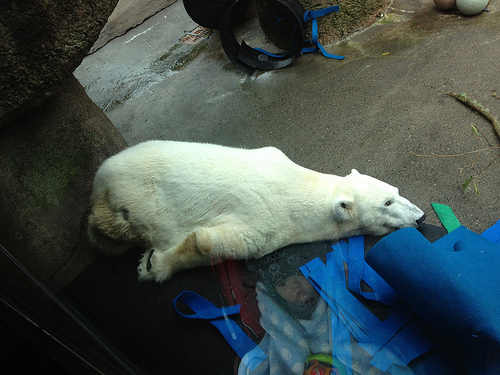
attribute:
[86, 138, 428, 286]
bear — white, big, laying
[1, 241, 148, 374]
wood — brown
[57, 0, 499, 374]
ground — scarred, hard, stone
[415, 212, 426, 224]
nose — black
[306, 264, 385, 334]
paper — blue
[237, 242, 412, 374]
child — reflected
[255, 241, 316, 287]
bandana — patterned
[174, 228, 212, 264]
spot — dark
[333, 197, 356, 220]
ear — small, white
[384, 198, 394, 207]
eye — black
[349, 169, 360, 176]
ear — white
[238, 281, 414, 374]
blanket — blue, white, polka dotted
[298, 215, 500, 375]
fabric — blue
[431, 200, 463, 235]
fabric — green